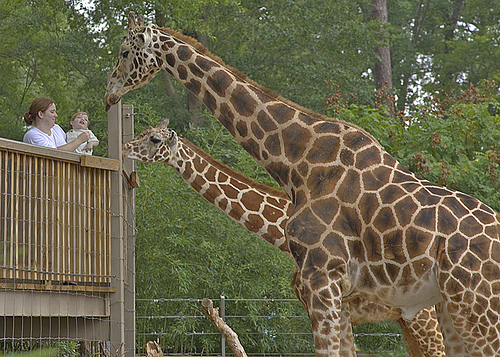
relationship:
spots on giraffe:
[309, 166, 341, 193] [74, 29, 476, 339]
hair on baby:
[65, 106, 99, 155] [65, 110, 100, 156]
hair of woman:
[24, 94, 47, 121] [27, 93, 73, 153]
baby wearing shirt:
[62, 109, 101, 156] [65, 127, 100, 155]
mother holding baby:
[20, 95, 90, 155] [66, 112, 100, 154]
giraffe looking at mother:
[100, 9, 499, 357] [20, 95, 90, 155]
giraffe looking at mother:
[122, 116, 452, 356] [20, 95, 90, 155]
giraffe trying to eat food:
[100, 9, 499, 357] [105, 114, 177, 188]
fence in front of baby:
[3, 144, 132, 321] [62, 109, 100, 157]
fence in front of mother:
[3, 144, 132, 321] [20, 95, 90, 155]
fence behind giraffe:
[134, 287, 416, 350] [100, 9, 499, 357]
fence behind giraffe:
[134, 287, 416, 350] [122, 115, 448, 355]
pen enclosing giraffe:
[3, 106, 498, 353] [122, 115, 448, 355]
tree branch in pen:
[198, 297, 247, 355] [3, 106, 498, 353]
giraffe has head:
[100, 9, 499, 357] [97, 12, 187, 111]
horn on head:
[137, 11, 148, 26] [97, 12, 187, 111]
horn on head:
[123, 10, 141, 24] [97, 12, 187, 111]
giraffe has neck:
[100, 9, 499, 357] [155, 26, 326, 187]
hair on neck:
[149, 30, 306, 130] [155, 26, 326, 187]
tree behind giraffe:
[0, 0, 498, 356] [100, 9, 499, 357]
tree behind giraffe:
[0, 0, 498, 356] [122, 115, 448, 355]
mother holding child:
[20, 95, 90, 155] [63, 106, 99, 161]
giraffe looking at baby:
[105, 22, 487, 306] [62, 109, 100, 157]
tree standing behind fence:
[0, 0, 498, 356] [135, 291, 405, 355]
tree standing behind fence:
[420, 0, 484, 97] [135, 291, 405, 355]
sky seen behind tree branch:
[66, 2, 498, 117] [212, 4, 268, 54]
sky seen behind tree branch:
[66, 2, 498, 117] [393, 1, 433, 121]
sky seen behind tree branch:
[66, 2, 498, 117] [32, 11, 104, 93]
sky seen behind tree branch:
[66, 2, 498, 117] [452, 16, 482, 29]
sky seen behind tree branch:
[66, 2, 498, 117] [320, 41, 378, 80]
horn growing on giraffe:
[137, 11, 149, 26] [100, 9, 499, 357]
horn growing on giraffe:
[123, 11, 139, 29] [100, 9, 499, 357]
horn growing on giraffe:
[156, 115, 172, 129] [122, 115, 448, 355]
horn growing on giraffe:
[154, 116, 164, 126] [122, 115, 448, 355]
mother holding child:
[22, 95, 90, 153] [59, 109, 99, 156]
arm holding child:
[30, 134, 87, 156] [59, 109, 99, 156]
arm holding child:
[51, 127, 91, 147] [59, 109, 99, 156]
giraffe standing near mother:
[100, 9, 499, 357] [20, 95, 90, 155]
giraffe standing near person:
[100, 9, 499, 357] [65, 107, 98, 156]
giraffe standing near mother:
[122, 115, 448, 355] [20, 95, 90, 155]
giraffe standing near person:
[122, 115, 448, 355] [65, 107, 98, 156]